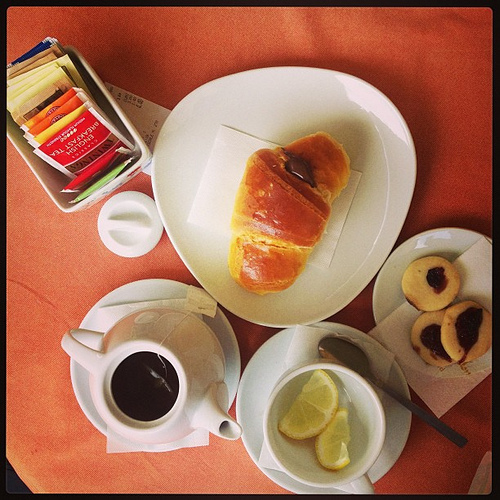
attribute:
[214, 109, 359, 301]
crossant — chocolate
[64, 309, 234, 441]
teapot — white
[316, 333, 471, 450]
metal spoon — grey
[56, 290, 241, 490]
kettle — small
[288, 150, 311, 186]
chocolate — melted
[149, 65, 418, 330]
plate — white, off shape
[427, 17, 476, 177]
table cloth — red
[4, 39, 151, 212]
container — white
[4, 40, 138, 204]
bags — tea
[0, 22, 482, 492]
table — orange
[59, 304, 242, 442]
teapot — white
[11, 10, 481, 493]
tablecloth — orange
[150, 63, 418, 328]
saucer — large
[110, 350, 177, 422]
drink — brewed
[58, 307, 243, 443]
pot — white, tea